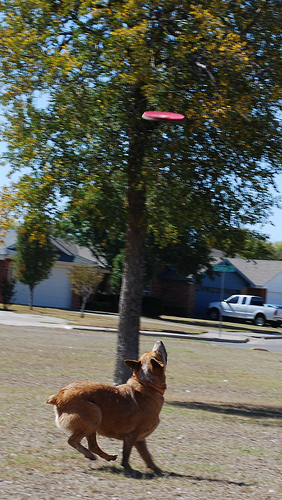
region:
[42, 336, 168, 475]
The brown dog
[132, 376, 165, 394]
The dog's orange collar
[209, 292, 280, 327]
White truck parked in a driveway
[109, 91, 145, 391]
Trunk of the tree near the dog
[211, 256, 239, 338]
The street sign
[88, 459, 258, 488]
The dog's shadow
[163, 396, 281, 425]
The shadow of the tree nearest the dog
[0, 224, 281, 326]
The houses across the street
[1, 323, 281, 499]
The grass field the dog is playing on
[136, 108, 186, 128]
The frisbee in the air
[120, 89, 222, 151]
the frisbee is red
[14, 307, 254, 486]
the dog is brown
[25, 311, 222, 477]
the dog is about to jump in the air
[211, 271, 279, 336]
the truck is white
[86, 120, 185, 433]
the tree is brown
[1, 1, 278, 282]
the trees leaves are green and yellow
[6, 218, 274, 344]
3 houses are pictured behind tree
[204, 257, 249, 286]
the sign is green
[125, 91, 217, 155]
the frisbee is in the air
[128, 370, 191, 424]
the dog's collar is red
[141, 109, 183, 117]
pink and white Frisbee in the air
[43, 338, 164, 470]
red dog on the lawn in the yard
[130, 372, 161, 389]
red collar around dog's neck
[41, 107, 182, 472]
red dog waiting to catch Frisbee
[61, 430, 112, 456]
dog's back feet off the ground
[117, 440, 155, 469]
dog's front feet on the ground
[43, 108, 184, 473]
dog standing in front of tree watching a pink Frisbee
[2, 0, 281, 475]
tall tree in the yard behind the dog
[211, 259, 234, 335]
street sign on the other side of street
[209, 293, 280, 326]
white truck parked before a blue garage door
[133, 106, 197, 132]
The disc is red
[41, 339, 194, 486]
The dog has a collar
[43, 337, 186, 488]
The dog is stopping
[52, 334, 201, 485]
This is a brown dog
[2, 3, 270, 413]
The dog is by the tree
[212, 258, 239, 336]
There is a street sign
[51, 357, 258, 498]
The dog casts a shadow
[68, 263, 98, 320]
The tree has yellow leaves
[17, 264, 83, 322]
The garage door is white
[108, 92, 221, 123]
the frisbee is red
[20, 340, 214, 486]
the dog is looking at the frisbee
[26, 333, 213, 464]
the dog is going to jump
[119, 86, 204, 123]
the frisbee is in the air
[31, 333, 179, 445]
the dog is reddish brown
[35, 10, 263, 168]
the leaves on the tree are green and yellow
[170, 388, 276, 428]
this is a shadow of a tree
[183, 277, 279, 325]
this is a white truck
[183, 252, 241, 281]
the street sign is green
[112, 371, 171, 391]
the dogs collar is orange